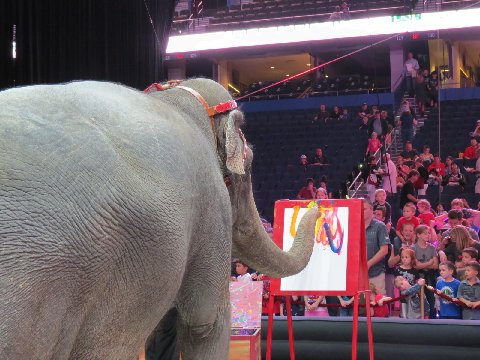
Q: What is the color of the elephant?
A: Gray.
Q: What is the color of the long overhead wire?
A: Pink.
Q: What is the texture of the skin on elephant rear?
A: Wrinkled.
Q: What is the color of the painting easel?
A: Red.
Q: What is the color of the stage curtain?
A: Dark brown.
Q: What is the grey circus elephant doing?
A: Performing.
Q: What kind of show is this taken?
A: Circus.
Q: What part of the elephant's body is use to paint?
A: Trunk.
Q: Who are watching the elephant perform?
A: Kids and adults.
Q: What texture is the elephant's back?
A: Wrinkles.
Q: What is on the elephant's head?
A: A harness.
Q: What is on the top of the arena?
A: Bright lights.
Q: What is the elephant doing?
A: Drawing a picture.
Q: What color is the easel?
A: Pink.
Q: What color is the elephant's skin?
A: Gray.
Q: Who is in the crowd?
A: Children.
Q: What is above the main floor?
A: A balcony.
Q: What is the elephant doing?
A: Painting a picture.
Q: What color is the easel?
A: Red.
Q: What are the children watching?
A: An elephant paint.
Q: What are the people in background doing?
A: Going up and down stairs.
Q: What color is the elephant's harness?
A: Red.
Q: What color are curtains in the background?
A: The curtains are black.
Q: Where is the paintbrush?
A: In the elephant's trunk.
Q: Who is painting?
A: The elephant.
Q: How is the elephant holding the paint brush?
A: In its trunk.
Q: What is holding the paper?
A: An easel.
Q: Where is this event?
A: At a circus.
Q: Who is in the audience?
A: People at the circus.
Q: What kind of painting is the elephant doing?
A: Abstract art.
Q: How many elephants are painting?
A: One.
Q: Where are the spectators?
A: In their seats.